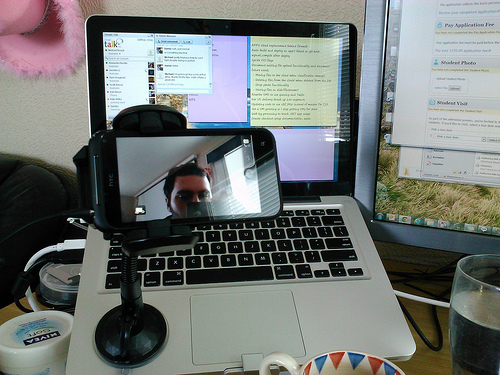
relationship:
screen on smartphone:
[117, 142, 244, 203] [92, 126, 282, 232]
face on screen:
[165, 167, 216, 208] [117, 142, 244, 203]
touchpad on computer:
[199, 298, 299, 347] [83, 19, 374, 288]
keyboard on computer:
[218, 231, 359, 270] [83, 19, 374, 288]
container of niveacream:
[6, 312, 74, 375] [23, 323, 68, 343]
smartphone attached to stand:
[92, 126, 282, 232] [109, 263, 169, 355]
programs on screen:
[229, 47, 333, 113] [92, 19, 354, 194]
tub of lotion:
[23, 323, 68, 343] [6, 312, 74, 375]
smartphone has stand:
[92, 126, 282, 232] [109, 263, 169, 355]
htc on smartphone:
[103, 170, 116, 190] [92, 126, 282, 232]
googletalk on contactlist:
[101, 61, 134, 87] [105, 61, 125, 115]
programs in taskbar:
[229, 47, 333, 113] [378, 211, 498, 237]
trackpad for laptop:
[199, 298, 299, 347] [83, 19, 374, 288]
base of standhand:
[96, 303, 173, 363] [91, 103, 213, 367]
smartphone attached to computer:
[92, 126, 474, 134] [83, 19, 374, 288]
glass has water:
[453, 258, 499, 365] [447, 305, 499, 366]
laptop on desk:
[83, 19, 374, 288] [3, 194, 499, 370]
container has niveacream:
[6, 312, 74, 375] [1, 309, 73, 375]